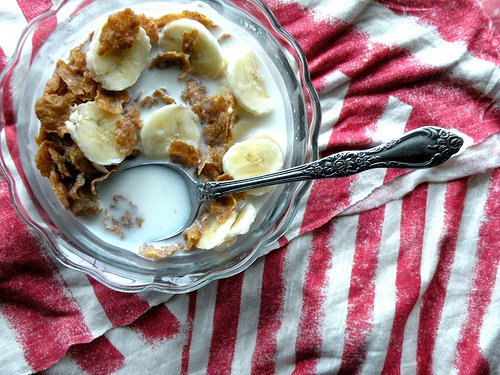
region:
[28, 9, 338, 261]
a bowl of cereals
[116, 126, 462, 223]
a silver spoon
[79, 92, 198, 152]
slices of bananas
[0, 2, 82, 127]
a bunch of cornflakes in a bowl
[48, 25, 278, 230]
a bowl of cornflakes with bananas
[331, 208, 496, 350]
a red and white striped towel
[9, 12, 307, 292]
a glass bowl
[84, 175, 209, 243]
a spoon full of milk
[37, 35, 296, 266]
a bowl of cereals with sliced bananas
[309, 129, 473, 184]
the delicately carved handle of a silver spoon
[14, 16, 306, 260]
Cereal in a bowl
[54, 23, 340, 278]
bananas in a bowl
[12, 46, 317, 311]
milk in a bowl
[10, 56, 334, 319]
a spoon in a bowl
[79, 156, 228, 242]
the bowl of a spoon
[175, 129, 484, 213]
the handle of a spoon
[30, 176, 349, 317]
A clear bowl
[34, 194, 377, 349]
A clear bowl on a striped towel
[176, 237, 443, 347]
Red and white stripes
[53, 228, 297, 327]
The edge of a clear bowl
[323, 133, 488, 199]
a metallic spoon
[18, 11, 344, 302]
a glass bowl in background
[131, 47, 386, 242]
milk in plate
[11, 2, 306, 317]
food in back ground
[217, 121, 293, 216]
bananas in the plate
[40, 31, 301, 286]
brown bran cereal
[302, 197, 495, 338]
a red and white fabric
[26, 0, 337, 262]
a bowl of cereal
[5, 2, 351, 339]
a delicous breakfast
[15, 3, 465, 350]
well made cereal in bowl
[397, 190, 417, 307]
Red stripe on a towel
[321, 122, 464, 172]
Handle of a silver colored spoon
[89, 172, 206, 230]
Milk and cereal in a spoon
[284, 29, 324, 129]
Rim of a glass bowl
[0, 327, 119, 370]
Edge of a white and red towel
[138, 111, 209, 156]
Banana slice in a bowl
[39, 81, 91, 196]
Brown cereal in a bowl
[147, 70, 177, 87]
Milk in a bowl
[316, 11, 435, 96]
Creased bunch on a red and white towel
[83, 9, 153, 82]
Piece of cereal on a banana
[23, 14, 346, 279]
cereal in a bowl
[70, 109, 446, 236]
A silver spoon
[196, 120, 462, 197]
The handle of a spoon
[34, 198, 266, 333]
the edge of a clear bowl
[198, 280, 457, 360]
red and white stripes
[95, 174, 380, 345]
A bowl on a striped towel